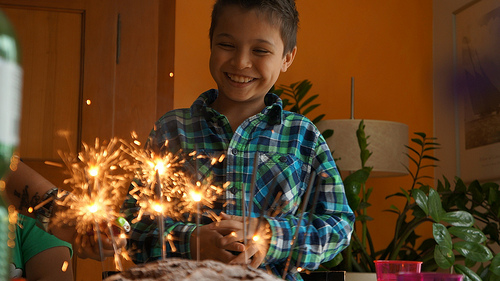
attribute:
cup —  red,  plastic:
[374, 257, 421, 278]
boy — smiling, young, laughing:
[114, 1, 357, 280]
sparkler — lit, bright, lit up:
[192, 171, 207, 267]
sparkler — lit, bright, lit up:
[148, 159, 169, 262]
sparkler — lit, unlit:
[243, 150, 270, 268]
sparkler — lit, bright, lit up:
[80, 190, 108, 279]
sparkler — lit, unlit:
[281, 167, 317, 280]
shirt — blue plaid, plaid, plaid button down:
[119, 89, 357, 280]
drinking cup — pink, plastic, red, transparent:
[372, 258, 425, 280]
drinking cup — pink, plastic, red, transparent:
[406, 272, 466, 280]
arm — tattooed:
[1, 152, 121, 254]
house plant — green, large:
[343, 176, 487, 280]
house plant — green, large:
[277, 79, 499, 235]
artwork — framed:
[431, 2, 499, 178]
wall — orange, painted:
[174, 2, 499, 261]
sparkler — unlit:
[294, 171, 326, 273]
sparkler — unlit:
[239, 179, 250, 267]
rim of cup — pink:
[370, 258, 426, 265]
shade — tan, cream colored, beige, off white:
[314, 117, 410, 177]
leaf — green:
[407, 185, 475, 226]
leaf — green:
[429, 221, 461, 266]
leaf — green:
[276, 77, 335, 143]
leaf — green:
[355, 117, 374, 169]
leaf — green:
[343, 164, 377, 211]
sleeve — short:
[16, 212, 76, 257]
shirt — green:
[0, 202, 74, 280]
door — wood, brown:
[2, 0, 125, 279]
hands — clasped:
[195, 209, 269, 271]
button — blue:
[229, 146, 243, 156]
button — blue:
[279, 154, 289, 163]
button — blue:
[230, 185, 240, 194]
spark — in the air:
[86, 97, 93, 107]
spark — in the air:
[131, 138, 144, 148]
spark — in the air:
[217, 153, 227, 163]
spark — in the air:
[26, 208, 34, 214]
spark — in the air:
[188, 150, 198, 158]